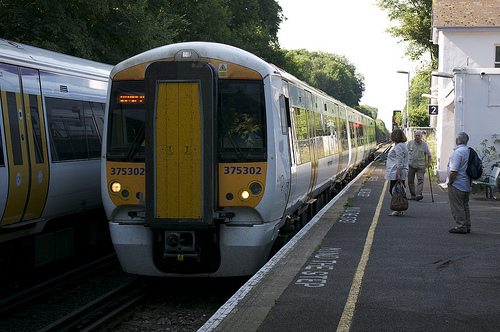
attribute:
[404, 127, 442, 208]
man — walking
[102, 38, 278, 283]
train front — orange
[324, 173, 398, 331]
line — yellow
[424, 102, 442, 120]
track — 2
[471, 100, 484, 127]
building — white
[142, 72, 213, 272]
door — yellow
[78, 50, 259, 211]
front — yellow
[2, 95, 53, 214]
doors — yellow and silver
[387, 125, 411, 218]
woman — white 